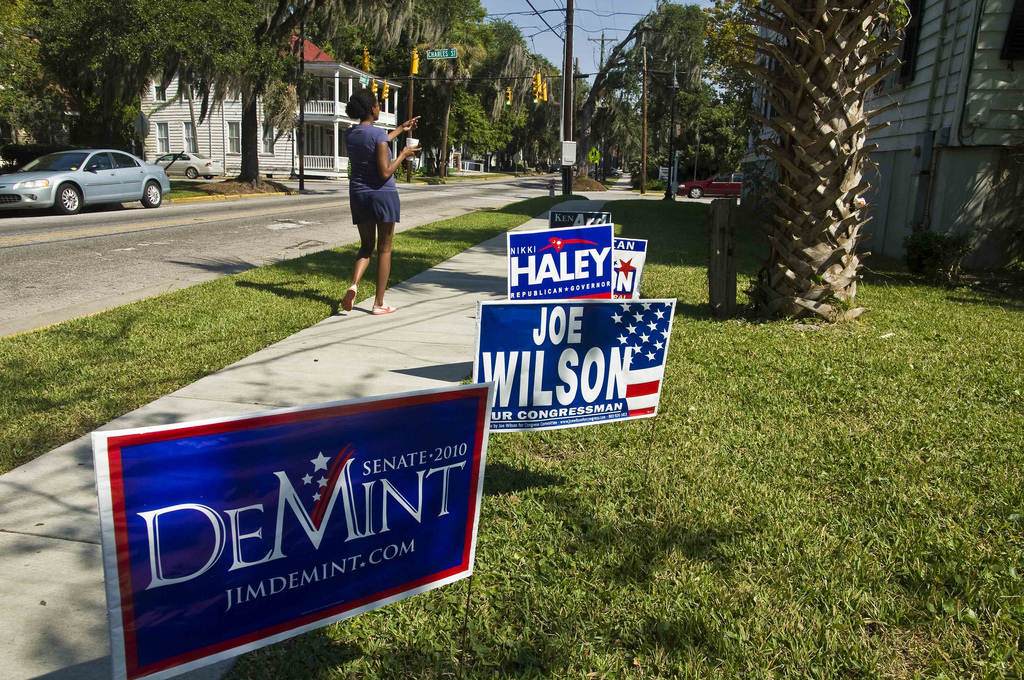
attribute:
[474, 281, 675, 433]
sign — political campaigning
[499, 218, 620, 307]
sign — political campaigning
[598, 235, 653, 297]
sign — political campaigning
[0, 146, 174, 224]
sedan — blue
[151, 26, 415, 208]
home — large, two-story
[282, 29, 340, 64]
roof — red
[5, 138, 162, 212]
car — blue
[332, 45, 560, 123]
lights — yellow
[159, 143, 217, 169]
car — white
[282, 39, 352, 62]
roof — red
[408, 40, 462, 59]
sign — green, street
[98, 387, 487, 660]
sign — white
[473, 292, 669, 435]
sign — joe wilson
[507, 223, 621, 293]
sign — haley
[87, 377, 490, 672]
sign — political campaigning, blue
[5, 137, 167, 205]
car — teal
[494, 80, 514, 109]
signal — street, green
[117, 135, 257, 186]
car — white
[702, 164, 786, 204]
car — red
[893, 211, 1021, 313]
bush — green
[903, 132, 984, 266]
meter — gray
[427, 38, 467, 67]
sign — green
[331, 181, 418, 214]
shorts — blue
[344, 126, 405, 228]
clothing — dark blue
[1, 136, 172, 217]
car — blue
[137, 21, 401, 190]
building — white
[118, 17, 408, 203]
house — white